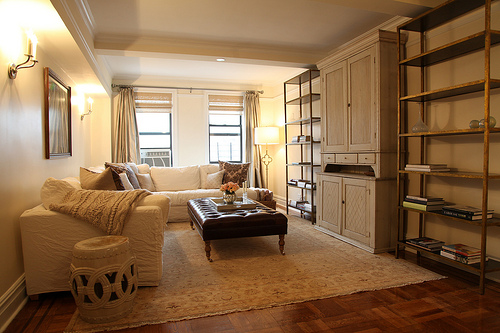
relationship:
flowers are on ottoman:
[219, 179, 240, 195] [185, 192, 296, 261]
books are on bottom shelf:
[403, 227, 487, 265] [391, 226, 500, 285]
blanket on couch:
[35, 175, 162, 237] [99, 158, 278, 226]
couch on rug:
[99, 158, 278, 226] [67, 199, 452, 331]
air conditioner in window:
[136, 145, 176, 171] [135, 97, 178, 169]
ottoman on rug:
[185, 192, 300, 265] [67, 199, 452, 331]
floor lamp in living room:
[246, 116, 284, 210] [6, 3, 498, 333]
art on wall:
[38, 63, 78, 167] [2, 0, 109, 329]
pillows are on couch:
[74, 156, 140, 198] [99, 158, 278, 226]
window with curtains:
[135, 97, 178, 169] [111, 81, 274, 195]